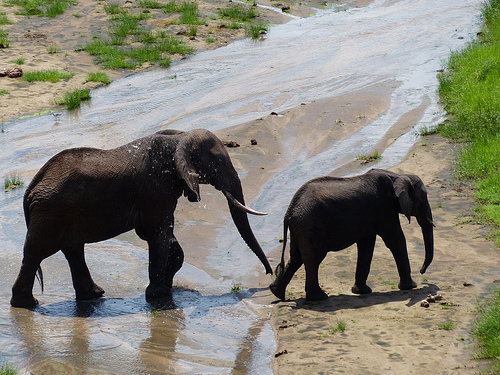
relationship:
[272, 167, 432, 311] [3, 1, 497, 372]
animal in field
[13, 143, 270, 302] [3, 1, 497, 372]
animal in field